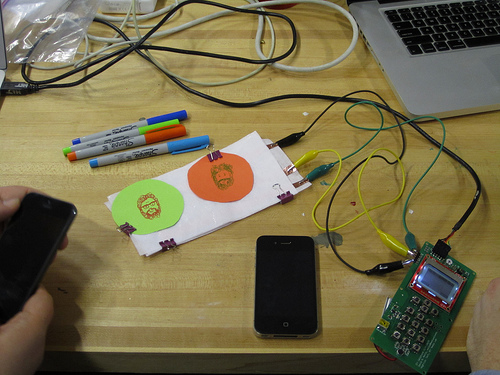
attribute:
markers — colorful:
[44, 130, 275, 215]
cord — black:
[246, 80, 413, 285]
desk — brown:
[105, 256, 248, 329]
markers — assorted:
[73, 115, 215, 177]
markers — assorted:
[54, 125, 205, 171]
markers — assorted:
[62, 106, 234, 180]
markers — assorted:
[69, 101, 259, 193]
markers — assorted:
[48, 112, 223, 201]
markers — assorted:
[29, 84, 213, 207]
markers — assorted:
[56, 115, 232, 193]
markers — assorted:
[73, 112, 213, 160]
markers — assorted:
[61, 117, 219, 179]